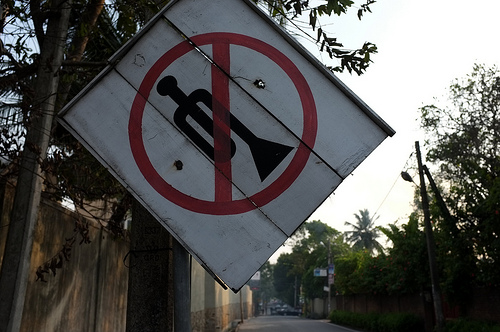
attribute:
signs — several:
[313, 265, 325, 277]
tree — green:
[422, 63, 498, 302]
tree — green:
[344, 209, 387, 274]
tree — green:
[275, 65, 499, 329]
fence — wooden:
[34, 203, 189, 330]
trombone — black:
[155, 75, 290, 177]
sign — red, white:
[80, 6, 381, 268]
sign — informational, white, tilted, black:
[57, 5, 398, 295]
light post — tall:
[399, 137, 449, 329]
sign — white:
[43, 0, 409, 302]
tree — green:
[437, 70, 498, 292]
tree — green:
[281, 251, 299, 278]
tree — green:
[411, 75, 498, 258]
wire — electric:
[359, 175, 407, 235]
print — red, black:
[129, 29, 319, 213]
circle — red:
[128, 32, 317, 215]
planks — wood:
[58, 4, 389, 289]